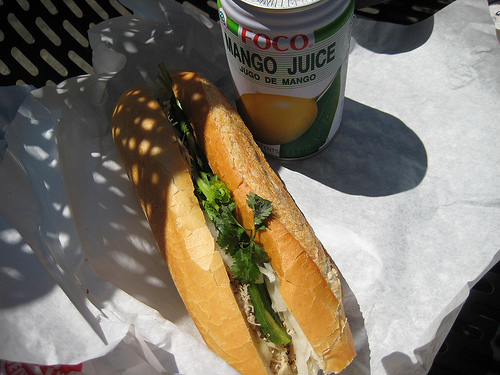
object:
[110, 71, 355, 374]
sandwhich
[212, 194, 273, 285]
lettuce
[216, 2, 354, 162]
can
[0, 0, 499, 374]
paper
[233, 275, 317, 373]
cheese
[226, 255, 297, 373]
meat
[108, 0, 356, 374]
lunch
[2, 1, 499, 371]
park bench